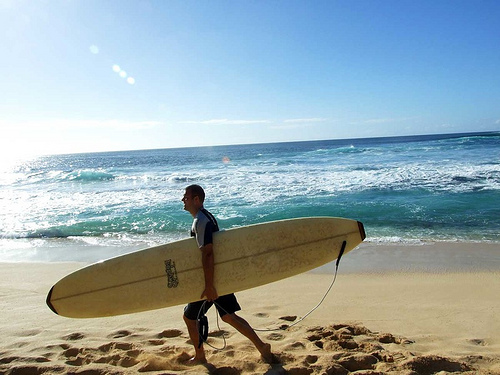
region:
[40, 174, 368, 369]
man carrying a surfboard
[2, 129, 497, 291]
ocean waves crashing onto a beach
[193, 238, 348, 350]
rope attached to a surfboard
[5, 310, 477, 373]
footprints in the sand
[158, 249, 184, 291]
surfboard manufacturer logo on surfboard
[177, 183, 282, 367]
man is facing left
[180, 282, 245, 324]
shorts on a surfer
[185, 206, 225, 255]
short sleeved shirt on a surfer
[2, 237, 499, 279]
wet sand next to the ocean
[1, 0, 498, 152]
clear blue cloudless sky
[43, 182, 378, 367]
man carrying surfboard on beach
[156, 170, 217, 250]
man wearing wetsuit on beach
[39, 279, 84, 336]
point of the surfboard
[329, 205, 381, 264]
end of the surfboard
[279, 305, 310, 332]
footprint in the sand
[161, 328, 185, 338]
footprint in the sand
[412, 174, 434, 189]
white waves in the ocean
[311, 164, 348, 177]
white waves in the ocean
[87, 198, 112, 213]
white waves in the ocean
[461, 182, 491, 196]
white waves in the ocean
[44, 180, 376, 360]
surfer carrying his surfboard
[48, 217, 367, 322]
white surfboard with black tips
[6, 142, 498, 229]
ocean behind surfer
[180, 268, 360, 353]
strap connected to surfboard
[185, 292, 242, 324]
black shorts of surfboarder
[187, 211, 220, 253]
black and gray shirt of surfboarder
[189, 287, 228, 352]
hand holding strap connected to surfboard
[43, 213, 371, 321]
black tips of surfboard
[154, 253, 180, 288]
black logo on surfboard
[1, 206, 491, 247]
ocean crashing onto beach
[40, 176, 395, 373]
A man carrying a surfboard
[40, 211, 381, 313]
A long white surfboard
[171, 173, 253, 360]
A man in a wet suit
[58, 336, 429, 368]
Footprints in the sand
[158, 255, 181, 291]
Words on a surfboard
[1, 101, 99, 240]
Sun shining on the water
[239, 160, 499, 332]
A sandy beach at the ocean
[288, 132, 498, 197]
Small waves in the ocean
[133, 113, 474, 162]
the horizon at the ocean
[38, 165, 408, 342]
A man walking with a surfboard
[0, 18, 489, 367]
beautiful beach scene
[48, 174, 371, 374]
man holding surf board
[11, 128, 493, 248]
beautiful blue ocean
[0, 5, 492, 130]
blue morning sky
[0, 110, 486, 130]
small line of clouds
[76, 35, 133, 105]
dots of sun beam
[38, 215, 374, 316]
white surf board with writing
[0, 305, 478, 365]
foot prints in the sand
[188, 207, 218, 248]
mans blue and grey shirt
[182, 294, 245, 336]
black board shorts